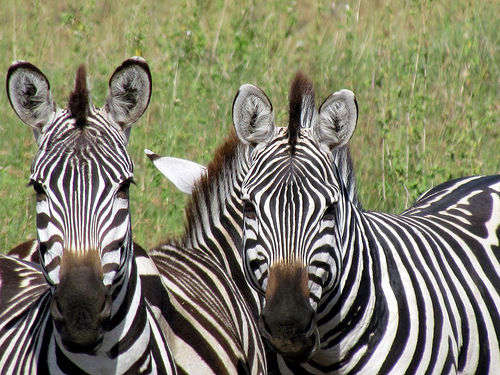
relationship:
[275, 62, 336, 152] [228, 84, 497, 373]
mane on a zebra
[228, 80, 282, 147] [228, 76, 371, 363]
ear on h head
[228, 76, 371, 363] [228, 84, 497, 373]
head of zebra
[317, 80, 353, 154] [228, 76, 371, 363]
ear on h head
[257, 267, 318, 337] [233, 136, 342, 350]
nose on h face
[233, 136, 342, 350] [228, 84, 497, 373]
face of zebra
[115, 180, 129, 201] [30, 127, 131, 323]
eye on h face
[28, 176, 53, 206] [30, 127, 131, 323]
eye on h face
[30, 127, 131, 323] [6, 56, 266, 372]
face of zebra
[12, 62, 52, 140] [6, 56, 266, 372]
ear of zebra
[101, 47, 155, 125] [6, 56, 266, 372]
ear of zebra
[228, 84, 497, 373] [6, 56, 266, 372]
zebra next to zebra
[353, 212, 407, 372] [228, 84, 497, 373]
stripe on zebra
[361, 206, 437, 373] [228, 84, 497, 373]
stripe on zebra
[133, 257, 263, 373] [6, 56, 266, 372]
stripe on zebra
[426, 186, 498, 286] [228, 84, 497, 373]
stripe on zebra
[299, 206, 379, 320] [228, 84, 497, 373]
stripe on zebra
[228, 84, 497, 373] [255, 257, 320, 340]
zebra has a nose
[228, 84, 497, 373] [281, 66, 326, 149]
zebra has a mane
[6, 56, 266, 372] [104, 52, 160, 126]
zebra has a ear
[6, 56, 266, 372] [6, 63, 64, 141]
zebra has a ear